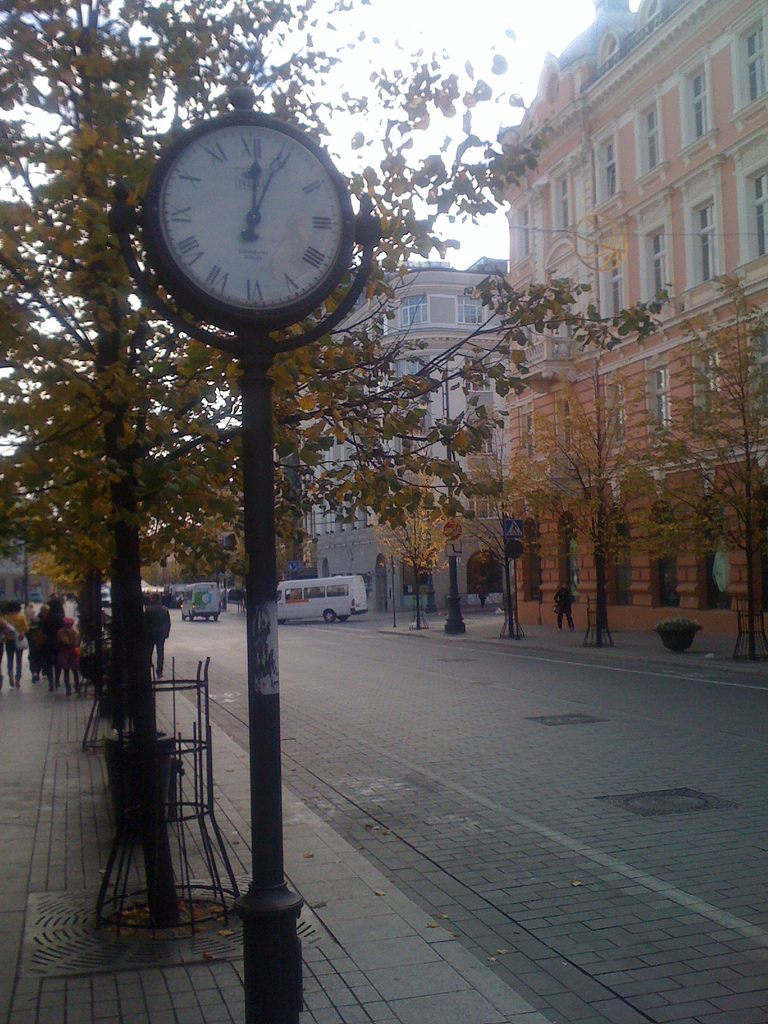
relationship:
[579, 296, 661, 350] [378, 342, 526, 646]
leaves on tree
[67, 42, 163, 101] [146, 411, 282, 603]
leaves on tree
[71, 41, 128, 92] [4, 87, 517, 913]
leaves on tree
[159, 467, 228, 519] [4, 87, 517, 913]
leaves on tree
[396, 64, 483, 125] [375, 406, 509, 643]
leaves on tree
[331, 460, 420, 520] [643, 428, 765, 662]
leaves on tree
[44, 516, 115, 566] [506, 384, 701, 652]
leaves on tree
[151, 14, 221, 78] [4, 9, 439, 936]
leaves on tree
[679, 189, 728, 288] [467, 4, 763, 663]
window on building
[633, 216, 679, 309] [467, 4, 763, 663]
window on building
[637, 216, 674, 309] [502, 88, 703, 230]
window on building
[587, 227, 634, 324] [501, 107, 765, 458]
window on building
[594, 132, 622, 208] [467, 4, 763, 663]
window on building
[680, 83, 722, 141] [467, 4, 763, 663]
window on building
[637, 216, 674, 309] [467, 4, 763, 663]
window on building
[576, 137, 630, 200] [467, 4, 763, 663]
window on building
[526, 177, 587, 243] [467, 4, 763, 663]
window on building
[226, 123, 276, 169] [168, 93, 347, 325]
numeral on clock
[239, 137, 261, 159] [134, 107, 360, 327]
numeral on clock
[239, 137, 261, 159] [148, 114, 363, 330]
numeral on clock